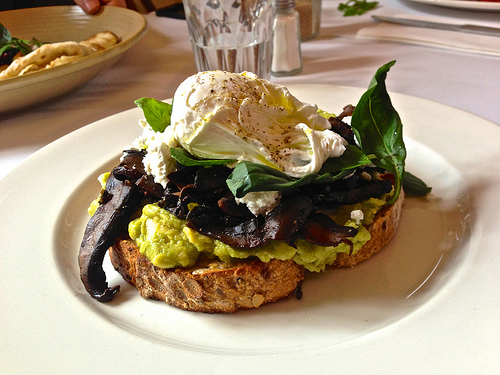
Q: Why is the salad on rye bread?
A: Its an open sandwich.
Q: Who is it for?
A: The guest.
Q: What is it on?
A: A plate.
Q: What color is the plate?
A: White.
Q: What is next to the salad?
A: A glass of water.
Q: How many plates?
A: One.